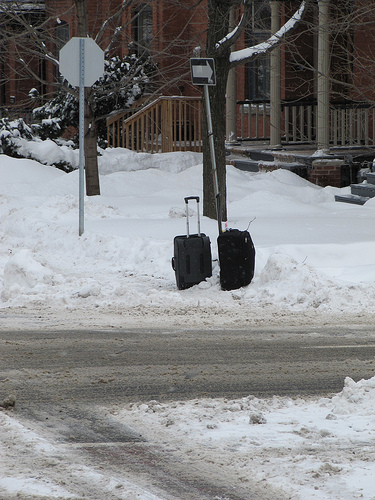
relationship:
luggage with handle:
[171, 179, 256, 296] [178, 193, 209, 234]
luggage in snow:
[171, 179, 256, 296] [16, 147, 366, 322]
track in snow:
[4, 322, 375, 499] [16, 147, 366, 322]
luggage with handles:
[171, 179, 256, 296] [178, 193, 209, 234]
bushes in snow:
[8, 11, 362, 151] [16, 147, 366, 322]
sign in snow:
[54, 32, 110, 235] [16, 147, 366, 322]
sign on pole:
[180, 55, 216, 85] [194, 85, 233, 225]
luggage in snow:
[175, 191, 212, 294] [26, 172, 171, 251]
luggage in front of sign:
[175, 191, 212, 294] [181, 51, 234, 233]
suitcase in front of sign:
[211, 229, 257, 291] [181, 51, 234, 233]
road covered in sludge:
[2, 268, 367, 409] [13, 291, 365, 336]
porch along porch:
[116, 95, 374, 165] [116, 83, 361, 167]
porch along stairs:
[116, 95, 374, 165] [339, 160, 372, 212]